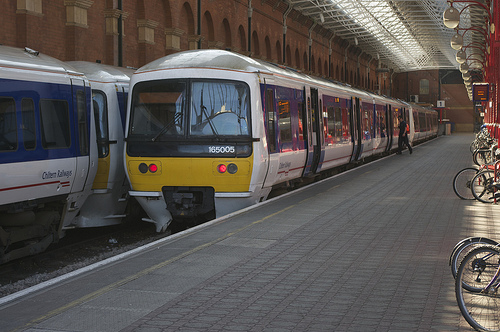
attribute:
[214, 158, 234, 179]
light — red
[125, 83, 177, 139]
window — large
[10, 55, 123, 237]
train — blue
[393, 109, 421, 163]
person — walking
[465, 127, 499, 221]
bikes — parked, standing, lined up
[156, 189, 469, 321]
ground — gray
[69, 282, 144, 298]
paint — yellow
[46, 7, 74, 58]
brick — brown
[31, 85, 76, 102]
paint — blue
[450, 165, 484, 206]
tire — round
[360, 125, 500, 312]
platform — grey, paved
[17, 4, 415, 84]
wall — bricked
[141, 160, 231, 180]
lights — red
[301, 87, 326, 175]
door — open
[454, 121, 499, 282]
bicycles — bunch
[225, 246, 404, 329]
gray — color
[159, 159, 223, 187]
yellow — color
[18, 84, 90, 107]
blue — color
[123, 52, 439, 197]
train — yellow, long, white, car, stopped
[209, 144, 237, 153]
numbers — white